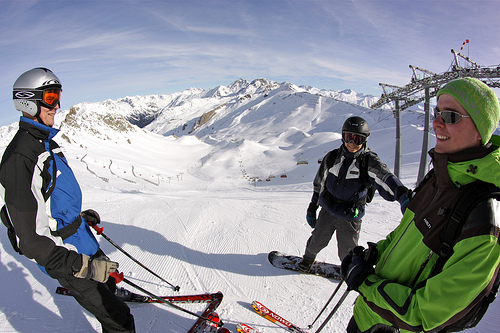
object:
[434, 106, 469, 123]
glasses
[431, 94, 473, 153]
face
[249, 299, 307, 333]
skiis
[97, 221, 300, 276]
shadow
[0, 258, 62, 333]
shadows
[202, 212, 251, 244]
snow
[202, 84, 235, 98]
hill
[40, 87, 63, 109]
goggles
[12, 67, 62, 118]
helmet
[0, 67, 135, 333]
man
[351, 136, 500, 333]
jacket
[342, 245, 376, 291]
gloves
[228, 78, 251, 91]
mountain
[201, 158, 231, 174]
snow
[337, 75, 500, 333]
adult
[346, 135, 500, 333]
suit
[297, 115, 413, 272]
adult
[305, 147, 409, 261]
suit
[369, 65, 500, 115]
ski lift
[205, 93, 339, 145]
mountain side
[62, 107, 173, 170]
mountain side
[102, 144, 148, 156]
snow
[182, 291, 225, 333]
snow ski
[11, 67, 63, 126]
head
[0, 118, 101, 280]
jacket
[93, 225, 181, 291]
ski pole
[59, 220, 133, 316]
hand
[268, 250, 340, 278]
skis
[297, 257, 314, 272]
feet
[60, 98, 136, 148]
mountain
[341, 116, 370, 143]
helmet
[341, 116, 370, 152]
head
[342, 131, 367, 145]
ski goggles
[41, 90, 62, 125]
face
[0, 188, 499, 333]
mountain top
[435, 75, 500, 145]
hat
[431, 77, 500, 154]
man's head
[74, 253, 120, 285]
gloves